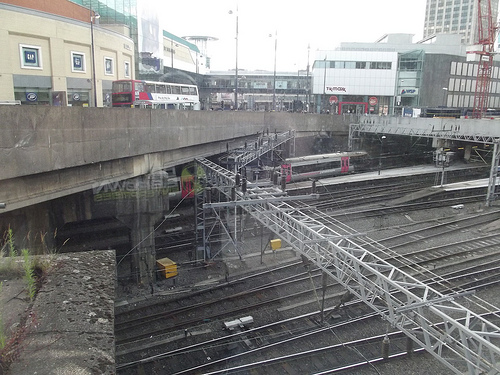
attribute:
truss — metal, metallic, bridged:
[231, 154, 473, 344]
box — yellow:
[153, 253, 181, 279]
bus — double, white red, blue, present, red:
[111, 75, 205, 107]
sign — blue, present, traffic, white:
[23, 51, 35, 61]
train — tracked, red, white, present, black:
[150, 148, 340, 197]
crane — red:
[467, 2, 499, 118]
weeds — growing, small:
[3, 220, 51, 285]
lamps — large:
[76, 0, 334, 105]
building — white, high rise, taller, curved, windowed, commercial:
[421, 5, 499, 111]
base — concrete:
[4, 92, 307, 182]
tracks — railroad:
[82, 203, 499, 374]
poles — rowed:
[210, 5, 330, 101]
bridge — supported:
[6, 91, 281, 171]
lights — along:
[83, 4, 109, 26]